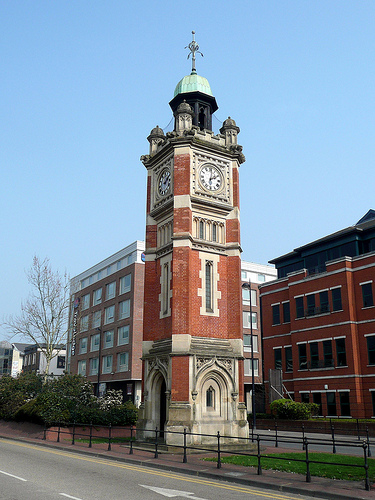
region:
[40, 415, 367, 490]
black metal fence surrounding old courtyard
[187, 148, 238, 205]
clock in tower old white and brown brick building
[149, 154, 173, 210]
side view of clock surrounded by grey cement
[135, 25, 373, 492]
old clock tower and court yard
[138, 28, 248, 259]
top of brick tower with at least two clock faces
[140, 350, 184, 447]
cement doorway to old clock tower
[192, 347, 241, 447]
window in old clock tower surrounded by decorative cement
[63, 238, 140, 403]
front of white and tan building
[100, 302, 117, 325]
window in tan building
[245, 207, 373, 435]
brown building with white trim and black top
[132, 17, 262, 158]
a building with a pointy spot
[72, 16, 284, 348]
a building with a clock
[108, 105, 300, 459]
a tower with a clock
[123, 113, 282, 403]
a tower wtih two clocks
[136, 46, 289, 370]
a brick building with two clocks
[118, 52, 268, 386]
a building with two clocks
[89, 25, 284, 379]
a building with two outside clocks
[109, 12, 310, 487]
a tall brick building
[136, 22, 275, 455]
a tall brick building with a pointy top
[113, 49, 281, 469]
a brick tower with windows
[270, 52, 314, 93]
part of the sky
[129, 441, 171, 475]
edge of a road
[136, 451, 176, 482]
edge of a road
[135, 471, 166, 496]
part of an arrow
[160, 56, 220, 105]
building's roof is blue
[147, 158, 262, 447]
the building is red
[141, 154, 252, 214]
2 clocks on building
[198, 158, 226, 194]
clock has black roman numerals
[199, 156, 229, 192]
clock is round shaped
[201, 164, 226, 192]
clock's hands are black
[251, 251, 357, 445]
building beside other building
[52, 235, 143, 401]
building behind other building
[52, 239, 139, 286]
top level of building is white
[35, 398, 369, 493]
metal railing beside building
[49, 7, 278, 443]
a tower in front a building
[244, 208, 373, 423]
a red building in front a tower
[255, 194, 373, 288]
roof of building is black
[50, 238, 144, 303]
roof of building is white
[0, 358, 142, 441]
bushes in front a building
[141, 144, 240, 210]
two clocks on a tower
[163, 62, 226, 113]
a small dome on top of tower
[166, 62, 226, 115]
dome is color green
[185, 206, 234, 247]
two small windows under a clock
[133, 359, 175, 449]
front door of tower